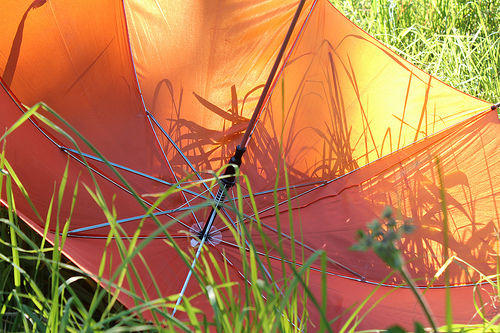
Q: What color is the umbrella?
A: Bright orange.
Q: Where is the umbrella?
A: In the grass.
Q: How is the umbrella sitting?
A: Upside down.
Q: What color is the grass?
A: Green.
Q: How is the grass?
A: It needs to be mowed.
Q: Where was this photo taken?
A: Outside in the grass.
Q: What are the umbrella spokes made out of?
A: Metal.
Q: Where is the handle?
A: On the umbrella.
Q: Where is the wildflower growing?
A: In the grass.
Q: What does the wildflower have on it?
A: Buds.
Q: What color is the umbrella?
A: Orange.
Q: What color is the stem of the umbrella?
A: Black.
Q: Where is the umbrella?
A: In a patch of grass.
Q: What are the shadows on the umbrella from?
A: Blades of grass.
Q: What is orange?
A: Umbrella.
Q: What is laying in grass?
A: Orange umbrella.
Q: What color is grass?
A: Green.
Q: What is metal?
A: Umbrella.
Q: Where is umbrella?
A: On ground.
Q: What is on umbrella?
A: Fabric.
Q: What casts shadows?
A: The grass.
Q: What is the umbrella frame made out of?
A: Metal.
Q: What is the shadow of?
A: Grass.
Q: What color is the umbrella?
A: Orange.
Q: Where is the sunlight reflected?
A: Off of the umbrella.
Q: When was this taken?
A: During the day time.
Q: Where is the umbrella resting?
A: In the grass.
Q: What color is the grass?
A: Green.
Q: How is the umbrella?
A: The umbrella is open.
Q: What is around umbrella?
A: Tall grass.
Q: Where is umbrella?
A: Grassy field.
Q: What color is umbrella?
A: Orangy red.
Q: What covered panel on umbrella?
A: Shadow.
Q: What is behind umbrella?
A: Grass.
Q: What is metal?
A: Umbrella spokes.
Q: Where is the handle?
A: On the umbrella.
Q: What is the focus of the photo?
A: An umbrella.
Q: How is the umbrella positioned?
A: Upside down.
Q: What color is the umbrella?
A: Orange.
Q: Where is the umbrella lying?
A: On the grass.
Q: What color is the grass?
A: Green.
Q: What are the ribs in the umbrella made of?
A: Metal.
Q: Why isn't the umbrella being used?
A: It's sunny.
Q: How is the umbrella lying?
A: Open.